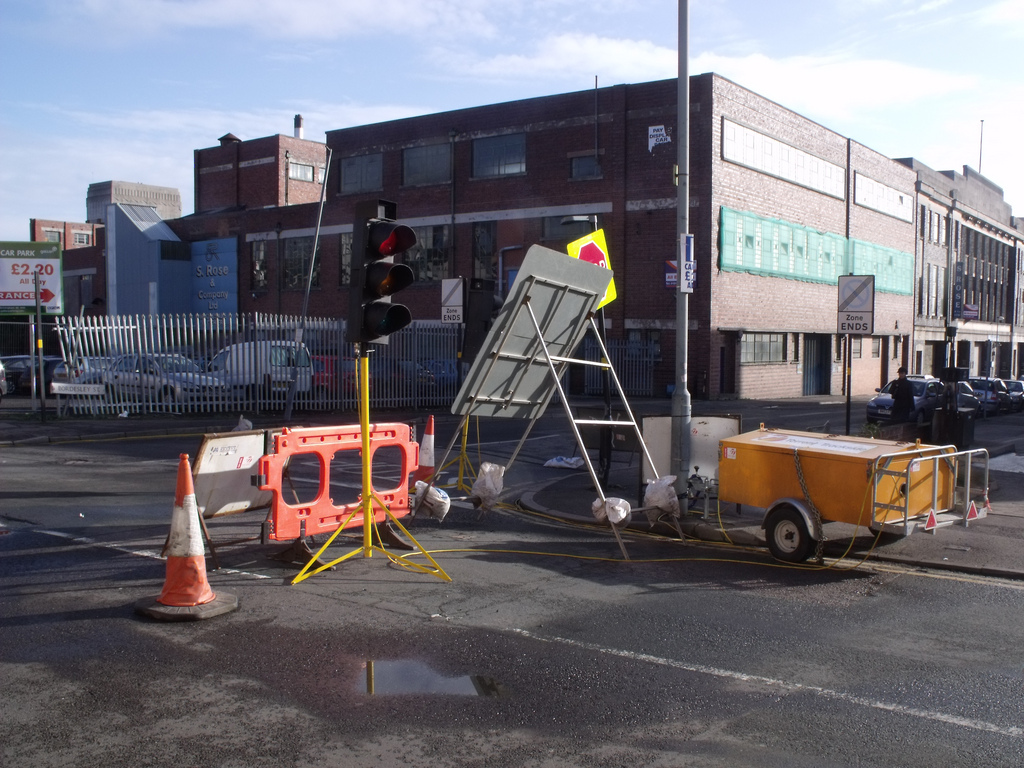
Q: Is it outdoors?
A: Yes, it is outdoors.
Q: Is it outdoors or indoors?
A: It is outdoors.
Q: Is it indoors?
A: No, it is outdoors.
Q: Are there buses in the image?
A: No, there are no buses.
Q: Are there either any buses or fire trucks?
A: No, there are no buses or fire trucks.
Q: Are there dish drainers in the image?
A: No, there are no dish drainers.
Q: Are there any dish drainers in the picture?
A: No, there are no dish drainers.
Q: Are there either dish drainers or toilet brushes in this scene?
A: No, there are no dish drainers or toilet brushes.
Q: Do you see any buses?
A: No, there are no buses.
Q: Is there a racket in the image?
A: No, there are no rackets.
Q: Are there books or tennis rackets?
A: No, there are no tennis rackets or books.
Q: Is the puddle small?
A: Yes, the puddle is small.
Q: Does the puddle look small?
A: Yes, the puddle is small.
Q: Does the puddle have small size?
A: Yes, the puddle is small.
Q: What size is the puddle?
A: The puddle is small.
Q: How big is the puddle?
A: The puddle is small.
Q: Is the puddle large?
A: No, the puddle is small.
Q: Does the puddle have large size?
A: No, the puddle is small.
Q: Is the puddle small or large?
A: The puddle is small.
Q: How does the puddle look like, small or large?
A: The puddle is small.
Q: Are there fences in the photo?
A: Yes, there is a fence.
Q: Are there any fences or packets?
A: Yes, there is a fence.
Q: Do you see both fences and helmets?
A: No, there is a fence but no helmets.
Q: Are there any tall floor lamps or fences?
A: Yes, there is a tall fence.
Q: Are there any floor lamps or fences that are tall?
A: Yes, the fence is tall.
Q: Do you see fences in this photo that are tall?
A: Yes, there is a tall fence.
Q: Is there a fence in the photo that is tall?
A: Yes, there is a fence that is tall.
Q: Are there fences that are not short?
A: Yes, there is a tall fence.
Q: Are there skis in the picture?
A: No, there are no skis.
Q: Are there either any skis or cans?
A: No, there are no skis or cans.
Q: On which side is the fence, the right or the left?
A: The fence is on the left of the image.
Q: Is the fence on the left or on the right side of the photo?
A: The fence is on the left of the image.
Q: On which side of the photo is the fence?
A: The fence is on the left of the image.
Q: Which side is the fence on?
A: The fence is on the left of the image.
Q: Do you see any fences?
A: Yes, there is a fence.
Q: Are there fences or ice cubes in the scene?
A: Yes, there is a fence.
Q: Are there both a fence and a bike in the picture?
A: No, there is a fence but no bikes.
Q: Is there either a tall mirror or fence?
A: Yes, there is a tall fence.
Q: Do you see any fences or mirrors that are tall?
A: Yes, the fence is tall.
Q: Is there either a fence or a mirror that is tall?
A: Yes, the fence is tall.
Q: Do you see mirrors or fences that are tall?
A: Yes, the fence is tall.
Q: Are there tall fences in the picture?
A: Yes, there is a tall fence.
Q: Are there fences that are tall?
A: Yes, there is a fence that is tall.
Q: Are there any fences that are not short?
A: Yes, there is a tall fence.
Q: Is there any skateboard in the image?
A: No, there are no skateboards.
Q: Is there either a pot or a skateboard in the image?
A: No, there are no skateboards or pots.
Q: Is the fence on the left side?
A: Yes, the fence is on the left of the image.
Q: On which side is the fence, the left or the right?
A: The fence is on the left of the image.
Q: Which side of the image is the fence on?
A: The fence is on the left of the image.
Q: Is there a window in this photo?
A: Yes, there is a window.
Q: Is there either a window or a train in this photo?
A: Yes, there is a window.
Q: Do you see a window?
A: Yes, there is a window.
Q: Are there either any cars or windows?
A: Yes, there is a window.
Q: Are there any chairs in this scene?
A: No, there are no chairs.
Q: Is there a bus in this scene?
A: No, there are no buses.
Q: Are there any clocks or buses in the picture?
A: No, there are no buses or clocks.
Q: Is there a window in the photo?
A: Yes, there is a window.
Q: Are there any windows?
A: Yes, there is a window.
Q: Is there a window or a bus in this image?
A: Yes, there is a window.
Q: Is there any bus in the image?
A: No, there are no buses.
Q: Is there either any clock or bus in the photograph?
A: No, there are no buses or clocks.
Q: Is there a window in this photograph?
A: Yes, there is a window.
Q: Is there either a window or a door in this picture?
A: Yes, there is a window.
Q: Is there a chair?
A: No, there are no chairs.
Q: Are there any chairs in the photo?
A: No, there are no chairs.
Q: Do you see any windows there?
A: Yes, there is a window.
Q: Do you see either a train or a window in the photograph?
A: Yes, there is a window.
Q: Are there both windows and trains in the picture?
A: No, there is a window but no trains.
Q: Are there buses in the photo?
A: No, there are no buses.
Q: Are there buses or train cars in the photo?
A: No, there are no buses or train cars.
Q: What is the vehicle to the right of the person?
A: The vehicle is a car.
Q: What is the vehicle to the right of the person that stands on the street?
A: The vehicle is a car.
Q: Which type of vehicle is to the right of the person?
A: The vehicle is a car.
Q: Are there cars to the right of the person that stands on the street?
A: Yes, there is a car to the right of the person.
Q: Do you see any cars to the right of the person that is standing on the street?
A: Yes, there is a car to the right of the person.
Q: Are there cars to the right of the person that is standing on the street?
A: Yes, there is a car to the right of the person.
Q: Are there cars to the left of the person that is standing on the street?
A: No, the car is to the right of the person.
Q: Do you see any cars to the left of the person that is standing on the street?
A: No, the car is to the right of the person.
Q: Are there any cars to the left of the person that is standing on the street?
A: No, the car is to the right of the person.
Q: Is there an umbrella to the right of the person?
A: No, there is a car to the right of the person.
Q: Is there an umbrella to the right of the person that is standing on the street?
A: No, there is a car to the right of the person.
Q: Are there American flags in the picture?
A: No, there are no American flags.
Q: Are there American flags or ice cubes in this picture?
A: No, there are no American flags or ice cubes.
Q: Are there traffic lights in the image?
A: Yes, there is a traffic light.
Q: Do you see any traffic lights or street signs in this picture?
A: Yes, there is a traffic light.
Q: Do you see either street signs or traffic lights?
A: Yes, there is a traffic light.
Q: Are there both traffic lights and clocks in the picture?
A: No, there is a traffic light but no clocks.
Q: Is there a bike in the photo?
A: No, there are no bikes.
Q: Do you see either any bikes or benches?
A: No, there are no bikes or benches.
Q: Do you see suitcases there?
A: No, there are no suitcases.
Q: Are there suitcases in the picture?
A: No, there are no suitcases.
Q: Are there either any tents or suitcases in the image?
A: No, there are no suitcases or tents.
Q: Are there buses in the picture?
A: No, there are no buses.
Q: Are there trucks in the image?
A: No, there are no trucks.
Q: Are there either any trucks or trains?
A: No, there are no trucks or trains.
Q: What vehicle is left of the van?
A: The vehicle is a car.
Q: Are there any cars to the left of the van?
A: Yes, there is a car to the left of the van.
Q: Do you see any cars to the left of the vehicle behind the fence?
A: Yes, there is a car to the left of the van.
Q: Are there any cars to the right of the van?
A: No, the car is to the left of the van.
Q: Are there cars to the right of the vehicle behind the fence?
A: No, the car is to the left of the van.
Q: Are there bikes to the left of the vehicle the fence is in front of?
A: No, there is a car to the left of the van.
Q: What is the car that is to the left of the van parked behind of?
A: The car is parked behind the fence.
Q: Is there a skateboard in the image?
A: No, there are no skateboards.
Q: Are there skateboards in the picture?
A: No, there are no skateboards.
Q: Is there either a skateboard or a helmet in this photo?
A: No, there are no skateboards or helmets.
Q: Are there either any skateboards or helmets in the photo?
A: No, there are no skateboards or helmets.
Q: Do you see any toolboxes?
A: No, there are no toolboxes.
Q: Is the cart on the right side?
A: Yes, the cart is on the right of the image.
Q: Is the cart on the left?
A: No, the cart is on the right of the image.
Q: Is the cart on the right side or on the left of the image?
A: The cart is on the right of the image.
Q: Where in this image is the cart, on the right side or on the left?
A: The cart is on the right of the image.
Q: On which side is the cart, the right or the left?
A: The cart is on the right of the image.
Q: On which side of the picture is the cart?
A: The cart is on the right of the image.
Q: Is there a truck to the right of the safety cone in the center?
A: No, there is a cart to the right of the cone.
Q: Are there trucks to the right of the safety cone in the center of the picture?
A: No, there is a cart to the right of the cone.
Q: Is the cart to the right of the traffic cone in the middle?
A: Yes, the cart is to the right of the cone.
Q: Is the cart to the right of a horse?
A: No, the cart is to the right of the cone.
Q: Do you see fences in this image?
A: Yes, there is a fence.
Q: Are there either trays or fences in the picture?
A: Yes, there is a fence.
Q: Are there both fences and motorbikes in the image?
A: No, there is a fence but no motorcycles.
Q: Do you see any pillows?
A: No, there are no pillows.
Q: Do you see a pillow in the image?
A: No, there are no pillows.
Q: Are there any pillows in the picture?
A: No, there are no pillows.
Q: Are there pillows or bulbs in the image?
A: No, there are no pillows or bulbs.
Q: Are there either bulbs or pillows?
A: No, there are no pillows or bulbs.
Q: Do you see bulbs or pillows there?
A: No, there are no pillows or bulbs.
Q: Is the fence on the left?
A: Yes, the fence is on the left of the image.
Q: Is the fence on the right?
A: No, the fence is on the left of the image.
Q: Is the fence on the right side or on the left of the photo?
A: The fence is on the left of the image.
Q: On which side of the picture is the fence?
A: The fence is on the left of the image.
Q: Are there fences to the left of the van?
A: Yes, there is a fence to the left of the van.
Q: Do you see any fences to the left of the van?
A: Yes, there is a fence to the left of the van.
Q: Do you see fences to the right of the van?
A: No, the fence is to the left of the van.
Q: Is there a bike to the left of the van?
A: No, there is a fence to the left of the van.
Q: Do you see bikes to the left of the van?
A: No, there is a fence to the left of the van.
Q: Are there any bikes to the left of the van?
A: No, there is a fence to the left of the van.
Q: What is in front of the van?
A: The fence is in front of the van.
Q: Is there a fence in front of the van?
A: Yes, there is a fence in front of the van.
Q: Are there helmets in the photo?
A: No, there are no helmets.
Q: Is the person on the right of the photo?
A: Yes, the person is on the right of the image.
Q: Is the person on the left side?
A: No, the person is on the right of the image.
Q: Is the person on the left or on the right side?
A: The person is on the right of the image.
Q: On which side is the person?
A: The person is on the right of the image.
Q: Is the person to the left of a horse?
A: No, the person is to the left of a car.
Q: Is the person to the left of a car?
A: Yes, the person is to the left of a car.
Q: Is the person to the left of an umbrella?
A: No, the person is to the left of a car.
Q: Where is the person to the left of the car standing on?
A: The person is standing on the street.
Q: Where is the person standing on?
A: The person is standing on the street.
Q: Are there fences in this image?
A: Yes, there is a fence.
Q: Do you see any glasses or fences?
A: Yes, there is a fence.